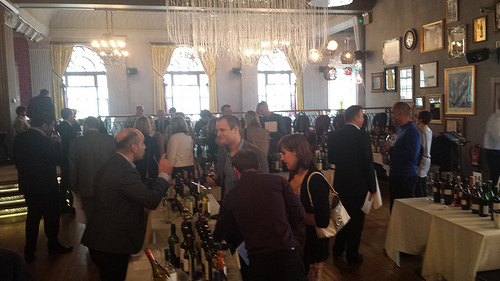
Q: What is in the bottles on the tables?
A: Wine.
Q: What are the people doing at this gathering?
A: Tasting wine.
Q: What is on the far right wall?
A: Assorted frames and memorabilia.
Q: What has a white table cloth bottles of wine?
A: The table.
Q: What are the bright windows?
A: Large.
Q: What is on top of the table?
A: Wines.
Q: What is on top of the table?
A: Wines.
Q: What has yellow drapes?
A: A window.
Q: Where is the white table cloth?
A: On the table.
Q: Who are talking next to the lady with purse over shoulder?
A: Two people talking to each other across the table with wine.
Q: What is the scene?
A: A people standing chatting and tasting wine.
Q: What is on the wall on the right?
A: Picture frames, clock and mirror.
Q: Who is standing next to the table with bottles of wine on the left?
A: A woman with a shoulder bag.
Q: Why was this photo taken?
A: To show a party.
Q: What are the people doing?
A: Drinking wine.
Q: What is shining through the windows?
A: Sunlight.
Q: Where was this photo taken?
A: In a party room.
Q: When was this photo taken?
A: In the daytime.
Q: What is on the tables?
A: Wine bottles.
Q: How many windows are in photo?
A: Four.